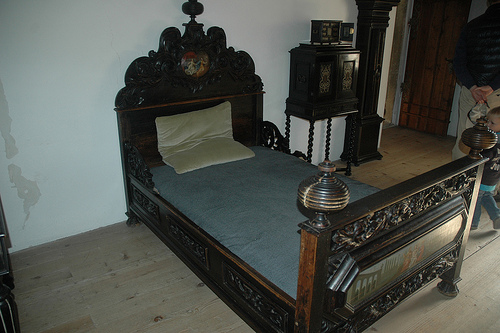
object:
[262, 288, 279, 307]
wood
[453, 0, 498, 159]
adult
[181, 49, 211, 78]
portrait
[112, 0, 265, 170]
headboard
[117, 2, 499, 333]
frame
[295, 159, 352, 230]
pole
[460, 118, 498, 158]
pole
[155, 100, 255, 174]
pillow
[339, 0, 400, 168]
clock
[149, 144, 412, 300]
mattress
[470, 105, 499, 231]
child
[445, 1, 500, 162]
person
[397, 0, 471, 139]
door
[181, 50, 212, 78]
clock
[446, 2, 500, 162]
man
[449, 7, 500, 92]
coat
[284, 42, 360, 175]
stand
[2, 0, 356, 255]
wall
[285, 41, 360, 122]
chest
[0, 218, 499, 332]
floor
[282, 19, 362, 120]
cabinet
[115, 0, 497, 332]
bed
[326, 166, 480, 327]
mural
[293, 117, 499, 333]
foot board